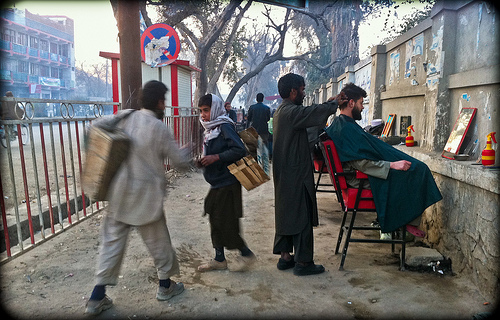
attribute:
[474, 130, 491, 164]
squirt bottle — red, yellow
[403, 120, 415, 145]
squirt bottle — red, yellow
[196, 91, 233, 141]
scarf — gray, head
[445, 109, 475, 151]
mirror — leaning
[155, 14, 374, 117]
branches — tree, leaveless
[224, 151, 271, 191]
purse — Brown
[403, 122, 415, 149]
spray bottle — red, yellow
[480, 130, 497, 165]
spray bottle — yellow, red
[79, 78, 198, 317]
man — light, gray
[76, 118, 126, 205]
basket — wooden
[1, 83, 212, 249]
fence — metal, red, white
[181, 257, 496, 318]
ground — below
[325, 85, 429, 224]
man w/smock — green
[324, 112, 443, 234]
cape — blue, barber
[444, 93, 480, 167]
mirror — leaning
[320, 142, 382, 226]
barber's chair — barber, red, black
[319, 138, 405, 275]
chair — red, barber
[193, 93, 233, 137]
scarf — gray, head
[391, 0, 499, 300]
wall — stone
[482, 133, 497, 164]
bottle — spray, red, yellow, stripes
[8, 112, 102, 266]
fence — white, rail